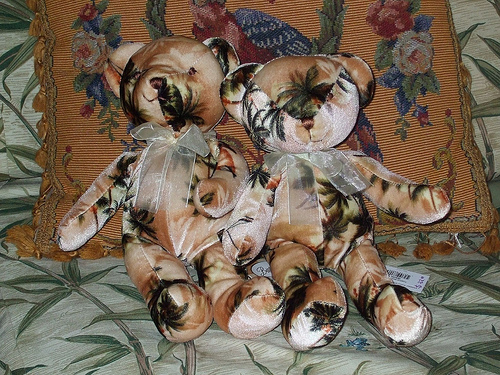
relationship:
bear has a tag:
[220, 54, 450, 351] [385, 262, 431, 297]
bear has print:
[220, 54, 450, 351] [227, 70, 332, 148]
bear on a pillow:
[220, 54, 450, 351] [9, 1, 498, 262]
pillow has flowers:
[9, 1, 498, 262] [364, 2, 440, 109]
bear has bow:
[220, 54, 450, 351] [259, 150, 366, 226]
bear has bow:
[59, 37, 288, 341] [131, 123, 211, 221]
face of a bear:
[225, 55, 375, 152] [220, 54, 450, 351]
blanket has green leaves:
[1, 2, 488, 373] [436, 258, 499, 328]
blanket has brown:
[1, 2, 488, 373] [74, 286, 149, 373]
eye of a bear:
[188, 67, 200, 77] [59, 37, 288, 341]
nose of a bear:
[296, 115, 325, 134] [220, 54, 450, 351]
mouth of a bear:
[283, 129, 335, 152] [220, 54, 450, 351]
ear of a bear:
[103, 38, 144, 100] [59, 37, 288, 341]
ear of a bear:
[204, 35, 244, 79] [59, 37, 288, 341]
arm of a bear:
[344, 144, 450, 227] [220, 54, 450, 351]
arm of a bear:
[225, 162, 277, 263] [220, 54, 450, 351]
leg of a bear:
[343, 247, 433, 351] [220, 54, 450, 351]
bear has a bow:
[220, 54, 450, 351] [259, 150, 366, 226]